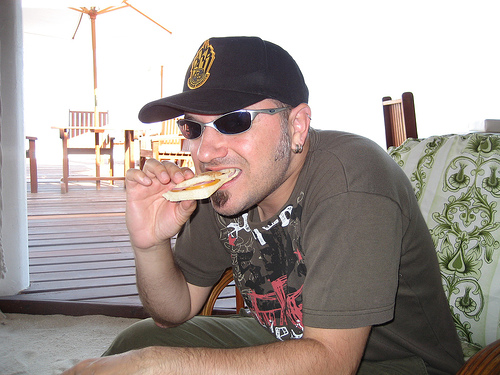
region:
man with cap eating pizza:
[125, 34, 315, 215]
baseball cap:
[138, 27, 311, 119]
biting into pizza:
[163, 160, 240, 202]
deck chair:
[51, 105, 120, 185]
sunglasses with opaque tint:
[175, 107, 290, 138]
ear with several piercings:
[285, 100, 311, 155]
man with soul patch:
[138, 35, 313, 215]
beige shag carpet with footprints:
[0, 300, 151, 372]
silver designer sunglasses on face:
[175, 105, 293, 140]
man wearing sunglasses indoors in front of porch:
[123, 29, 448, 324]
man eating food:
[61, 31, 468, 370]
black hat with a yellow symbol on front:
[134, 38, 310, 123]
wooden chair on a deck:
[60, 108, 115, 185]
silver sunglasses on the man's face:
[177, 102, 292, 137]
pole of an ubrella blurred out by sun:
[63, 1, 171, 98]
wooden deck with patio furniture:
[28, 167, 149, 315]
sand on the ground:
[1, 313, 146, 373]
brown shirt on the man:
[175, 128, 456, 365]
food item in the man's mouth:
[159, 172, 237, 198]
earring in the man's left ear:
[295, 144, 302, 153]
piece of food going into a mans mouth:
[162, 157, 245, 208]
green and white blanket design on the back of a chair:
[376, 118, 498, 350]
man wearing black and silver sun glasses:
[165, 93, 298, 151]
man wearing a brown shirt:
[105, 128, 440, 373]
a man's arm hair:
[115, 327, 340, 371]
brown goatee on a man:
[207, 184, 231, 206]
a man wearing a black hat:
[132, 25, 307, 130]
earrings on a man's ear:
[292, 98, 311, 156]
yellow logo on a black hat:
[175, 33, 220, 99]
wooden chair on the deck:
[49, 93, 131, 189]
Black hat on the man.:
[153, 19, 350, 221]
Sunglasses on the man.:
[169, 104, 301, 143]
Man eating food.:
[106, 33, 357, 318]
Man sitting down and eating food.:
[110, 24, 435, 374]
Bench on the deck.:
[59, 65, 156, 205]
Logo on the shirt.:
[159, 147, 385, 369]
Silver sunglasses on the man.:
[141, 74, 354, 164]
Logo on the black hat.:
[153, 28, 246, 115]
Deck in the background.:
[35, 191, 135, 338]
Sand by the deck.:
[36, 295, 131, 372]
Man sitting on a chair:
[62, 35, 494, 374]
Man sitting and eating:
[57, 35, 467, 372]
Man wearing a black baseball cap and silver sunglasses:
[56, 34, 466, 372]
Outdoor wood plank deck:
[1, 151, 256, 316]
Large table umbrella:
[20, 4, 176, 186]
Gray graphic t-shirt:
[167, 122, 466, 374]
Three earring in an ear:
[290, 102, 313, 154]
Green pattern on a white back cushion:
[384, 130, 499, 365]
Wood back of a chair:
[379, 91, 419, 149]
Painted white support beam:
[0, 1, 30, 301]